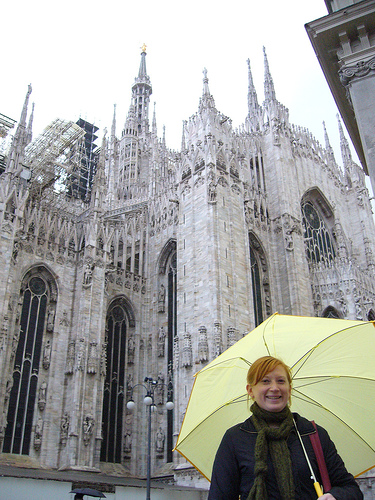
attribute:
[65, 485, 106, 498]
umbrella — black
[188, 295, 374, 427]
umbrella — yellow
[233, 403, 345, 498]
scarf — green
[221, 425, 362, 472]
jacket — black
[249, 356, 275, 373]
hair — red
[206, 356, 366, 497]
woman — smiling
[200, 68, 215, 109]
point — decorative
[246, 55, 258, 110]
point — decorative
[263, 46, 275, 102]
point — decorative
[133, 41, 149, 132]
point — decorative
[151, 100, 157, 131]
point — decorative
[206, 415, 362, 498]
jacket — blue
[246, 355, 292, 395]
hair — red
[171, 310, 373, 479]
umbrella — yellow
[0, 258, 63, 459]
window — tall, skinny, arched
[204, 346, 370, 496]
woman — standing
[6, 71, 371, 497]
white building — large, brick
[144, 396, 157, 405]
light — white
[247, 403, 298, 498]
scarf — green